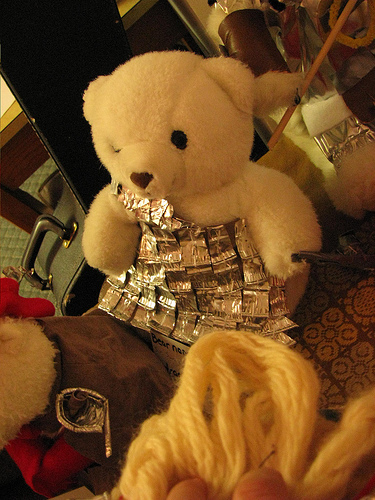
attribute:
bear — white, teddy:
[76, 47, 322, 332]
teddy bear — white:
[80, 53, 320, 349]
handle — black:
[17, 213, 78, 290]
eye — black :
[170, 128, 189, 151]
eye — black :
[109, 144, 122, 154]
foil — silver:
[96, 181, 300, 349]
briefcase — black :
[20, 183, 104, 314]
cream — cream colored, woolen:
[235, 430, 269, 456]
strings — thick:
[177, 414, 212, 456]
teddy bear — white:
[61, 50, 320, 392]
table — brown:
[5, 136, 39, 181]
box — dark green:
[15, 178, 102, 314]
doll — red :
[1, 273, 53, 323]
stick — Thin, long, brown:
[268, 0, 357, 144]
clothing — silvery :
[89, 172, 299, 349]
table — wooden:
[11, 133, 38, 159]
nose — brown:
[123, 149, 163, 205]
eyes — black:
[164, 126, 193, 153]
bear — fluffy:
[79, 56, 324, 313]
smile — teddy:
[129, 176, 187, 202]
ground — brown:
[287, 255, 373, 419]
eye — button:
[170, 130, 188, 149]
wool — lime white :
[128, 334, 351, 479]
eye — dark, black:
[163, 125, 192, 153]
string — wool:
[178, 383, 205, 476]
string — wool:
[183, 339, 211, 483]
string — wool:
[212, 344, 234, 499]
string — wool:
[212, 346, 246, 499]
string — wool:
[300, 361, 315, 478]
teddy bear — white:
[82, 50, 320, 312]